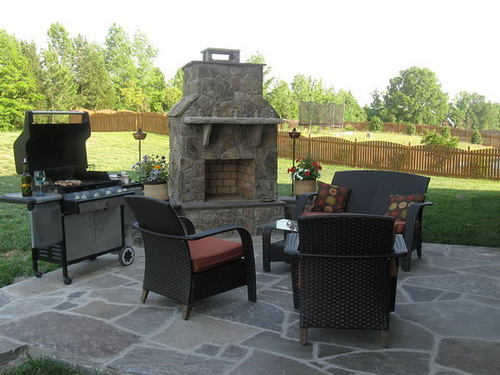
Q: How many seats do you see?
A: Three.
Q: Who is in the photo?
A: Nobody.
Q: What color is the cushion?
A: Red/orange.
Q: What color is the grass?
A: Green.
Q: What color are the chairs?
A: Brown.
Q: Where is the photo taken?
A: Backyard.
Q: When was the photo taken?
A: Daytime.